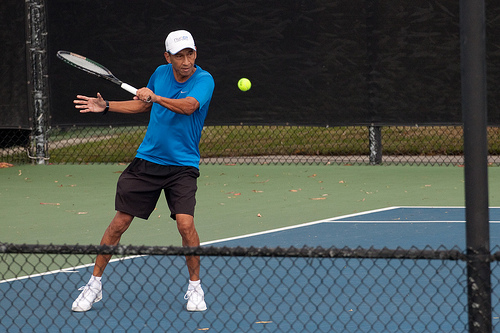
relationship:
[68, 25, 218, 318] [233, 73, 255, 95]
man hitting ball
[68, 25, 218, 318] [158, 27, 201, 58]
man has hat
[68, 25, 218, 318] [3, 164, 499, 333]
man on top of tennis court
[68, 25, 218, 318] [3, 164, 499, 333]
man playing on tennis court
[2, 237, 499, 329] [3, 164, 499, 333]
fence on side of tennis court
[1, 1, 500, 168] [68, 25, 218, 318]
fence behind man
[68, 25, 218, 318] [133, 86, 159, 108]
man has hand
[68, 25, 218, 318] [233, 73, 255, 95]
man swing at ball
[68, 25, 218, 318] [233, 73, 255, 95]
man swinging at ball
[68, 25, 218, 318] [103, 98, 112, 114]
man with wristwatch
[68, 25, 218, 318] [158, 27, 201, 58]
man wearing hat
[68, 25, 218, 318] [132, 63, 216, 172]
man wearing shirt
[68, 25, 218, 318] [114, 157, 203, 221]
man wearing shorts